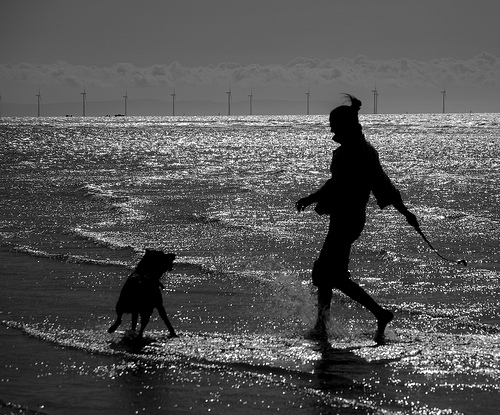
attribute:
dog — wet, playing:
[96, 240, 190, 343]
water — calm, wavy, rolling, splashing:
[1, 117, 496, 413]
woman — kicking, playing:
[290, 92, 470, 357]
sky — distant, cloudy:
[0, 0, 500, 111]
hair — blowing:
[324, 86, 367, 120]